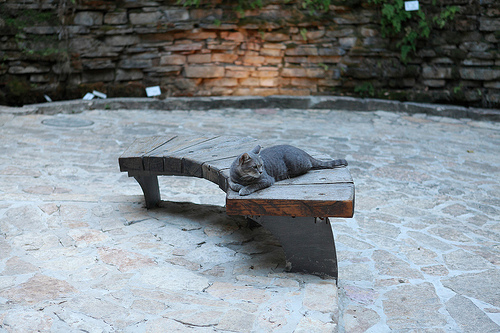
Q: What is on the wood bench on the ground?
A: There is a cat sitting on the wood bench on the ground.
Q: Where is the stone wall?
A: The stone wall is by the bench.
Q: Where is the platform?
A: The platform is on the ground.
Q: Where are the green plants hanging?
A: The green plants are hanging on the wall.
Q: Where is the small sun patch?
A: The sun patch is on the top of the wall.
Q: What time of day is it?
A: It is daytime.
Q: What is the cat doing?
A: The cat is laying down.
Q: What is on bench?
A: Cat.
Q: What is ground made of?
A: Rocks and concrete.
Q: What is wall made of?
A: Rocks and brick.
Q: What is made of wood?
A: Bench.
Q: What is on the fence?
A: Plants.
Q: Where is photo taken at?
A: Taken outside.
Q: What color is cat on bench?
A: Gray.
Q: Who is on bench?
A: A cat.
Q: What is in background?
A: Wall stacked by stones.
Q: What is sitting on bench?
A: Cat.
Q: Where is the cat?
A: On bench.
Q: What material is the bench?
A: Wood and concrete.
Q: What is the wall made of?
A: Stones.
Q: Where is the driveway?
A: Between bench and wall.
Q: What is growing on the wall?
A: Vegetation.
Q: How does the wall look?
A: Very old.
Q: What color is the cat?
A: Gray.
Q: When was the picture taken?
A: Bright day.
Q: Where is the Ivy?
A: CCI4THe Ivy is growing against the wall.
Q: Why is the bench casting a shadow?
A: Because of the time of day, and the position of the sun.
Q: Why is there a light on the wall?
A: Because the sun is hitting it.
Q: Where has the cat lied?
A: On the bench.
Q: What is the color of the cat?
A: Gray.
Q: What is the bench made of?
A: Wood.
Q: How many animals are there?
A: 1.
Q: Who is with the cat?
A: No one.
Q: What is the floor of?
A: Stone.